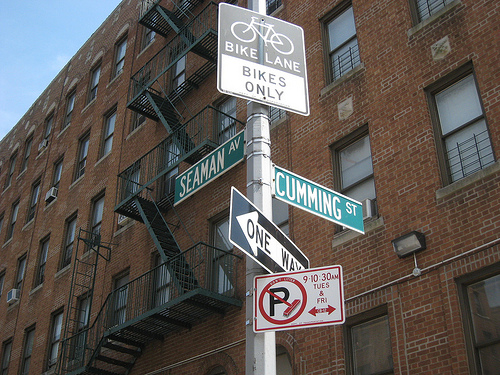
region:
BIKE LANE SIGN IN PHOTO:
[207, 5, 337, 116]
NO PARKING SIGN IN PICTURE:
[250, 265, 355, 330]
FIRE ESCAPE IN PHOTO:
[116, 5, 241, 365]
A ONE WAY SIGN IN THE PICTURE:
[211, 182, 316, 274]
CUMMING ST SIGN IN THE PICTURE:
[266, 157, 376, 234]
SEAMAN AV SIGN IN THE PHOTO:
[162, 125, 259, 205]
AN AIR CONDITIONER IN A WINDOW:
[35, 145, 66, 205]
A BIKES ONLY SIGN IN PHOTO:
[213, 1, 313, 117]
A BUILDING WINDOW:
[414, 62, 495, 201]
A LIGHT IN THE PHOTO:
[383, 227, 430, 280]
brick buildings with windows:
[11, 22, 169, 352]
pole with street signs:
[180, 0, 360, 370]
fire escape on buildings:
[96, 15, 221, 360]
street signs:
[150, 101, 410, 256]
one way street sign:
[205, 197, 326, 277]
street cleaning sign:
[215, 260, 361, 350]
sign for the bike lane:
[185, 0, 332, 116]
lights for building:
[352, 235, 487, 325]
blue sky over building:
[3, 7, 104, 134]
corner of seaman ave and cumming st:
[143, 78, 414, 251]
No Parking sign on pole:
[251, 266, 349, 328]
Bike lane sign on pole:
[212, 2, 310, 114]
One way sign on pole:
[226, 185, 303, 273]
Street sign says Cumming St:
[278, 162, 361, 232]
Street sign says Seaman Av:
[176, 130, 243, 202]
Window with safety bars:
[421, 80, 497, 190]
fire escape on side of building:
[70, 192, 230, 373]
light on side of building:
[381, 235, 440, 275]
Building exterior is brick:
[369, 72, 442, 217]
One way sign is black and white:
[227, 187, 312, 274]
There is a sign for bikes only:
[216, 3, 313, 120]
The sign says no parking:
[251, 267, 358, 349]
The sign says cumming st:
[274, 163, 399, 225]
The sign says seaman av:
[168, 135, 268, 182]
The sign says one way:
[226, 196, 334, 286]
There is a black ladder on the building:
[63, 231, 93, 373]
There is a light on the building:
[391, 233, 438, 279]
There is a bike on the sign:
[223, 6, 328, 128]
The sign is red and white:
[252, 273, 355, 343]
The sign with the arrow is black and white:
[226, 196, 326, 287]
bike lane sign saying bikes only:
[202, 1, 317, 118]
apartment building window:
[409, 47, 497, 209]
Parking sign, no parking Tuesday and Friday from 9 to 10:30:
[241, 259, 352, 342]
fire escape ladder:
[52, 215, 136, 374]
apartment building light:
[381, 225, 442, 297]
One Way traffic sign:
[212, 183, 328, 302]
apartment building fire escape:
[112, 0, 239, 373]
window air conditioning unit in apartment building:
[38, 182, 71, 209]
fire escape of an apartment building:
[93, 11, 241, 329]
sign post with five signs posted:
[198, 0, 329, 373]